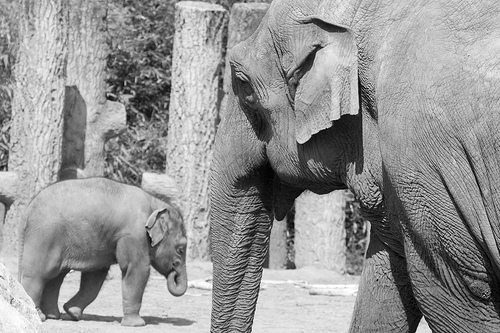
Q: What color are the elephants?
A: Gray.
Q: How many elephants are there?
A: Two.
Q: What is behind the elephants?
A: Trees.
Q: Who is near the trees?
A: The baby elephant.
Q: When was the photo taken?
A: Daytime.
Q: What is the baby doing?
A: Walking.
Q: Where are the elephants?
A: In front of the trees.